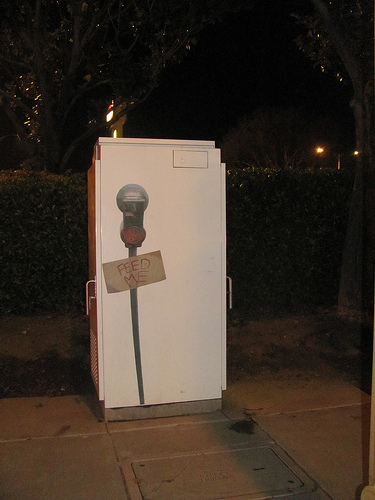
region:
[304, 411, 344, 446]
part of a walking path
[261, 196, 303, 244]
part of a fence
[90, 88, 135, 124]
part of some tree branches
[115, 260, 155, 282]
part of a poster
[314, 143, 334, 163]
part of a glowing light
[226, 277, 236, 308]
part of a metal handle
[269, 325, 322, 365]
part of the ground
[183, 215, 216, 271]
part of a white surface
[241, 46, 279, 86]
part of the dark sky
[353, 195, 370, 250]
stem of a tree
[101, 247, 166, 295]
a brown painted sign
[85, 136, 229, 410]
a white structure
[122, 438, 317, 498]
a gray panel on the sidewalk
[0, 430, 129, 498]
a gray cement slab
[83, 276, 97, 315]
a handle on the structure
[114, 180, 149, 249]
a gray painted parking meter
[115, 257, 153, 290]
red writing on the sign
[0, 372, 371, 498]
a gray cement sidewalk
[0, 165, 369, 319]
a tall green hedge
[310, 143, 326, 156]
a yellow light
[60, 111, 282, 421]
A white box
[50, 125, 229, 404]
A white box with a sign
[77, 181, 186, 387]
A white box with a cardboard sign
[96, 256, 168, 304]
A cardboard sign with red letters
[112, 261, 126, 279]
A red letter "F"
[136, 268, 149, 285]
A red letter "E"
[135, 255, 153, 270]
A red letter "D"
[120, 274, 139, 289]
A red letter "M"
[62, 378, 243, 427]
The bottom of a white box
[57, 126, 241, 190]
The top of a white box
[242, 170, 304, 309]
this is a fence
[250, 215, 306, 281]
the fence is made of leaves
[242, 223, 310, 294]
the leaves are green in color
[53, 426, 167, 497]
this is the ground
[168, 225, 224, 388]
this is a electricity booth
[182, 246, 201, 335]
the booth is white in color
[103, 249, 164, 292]
this is a cardboard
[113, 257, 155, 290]
the cardboard has some writings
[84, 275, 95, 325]
this is the booth handle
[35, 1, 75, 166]
this is a tree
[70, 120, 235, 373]
Sticker on the side of locker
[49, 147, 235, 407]
A electric cabinet for traffic signals.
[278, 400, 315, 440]
Sidewalk made out of cement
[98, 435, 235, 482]
Access lid on the sidewalk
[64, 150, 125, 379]
Door for the electrical box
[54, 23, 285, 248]
Night time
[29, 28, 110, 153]
Tree in the background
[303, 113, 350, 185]
Street lights at night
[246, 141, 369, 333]
Trimmed shrubs along the sidewalk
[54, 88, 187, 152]
A sign that is lite up